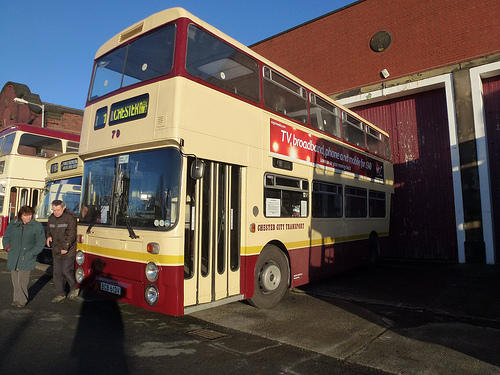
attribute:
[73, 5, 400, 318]
bus — tall, tan, red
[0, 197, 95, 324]
people — walking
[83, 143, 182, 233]
window — clean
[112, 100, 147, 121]
sign — electronic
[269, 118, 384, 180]
sign — electronic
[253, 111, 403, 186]
sign — red, white